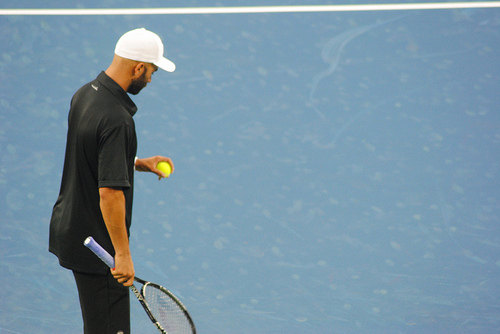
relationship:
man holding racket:
[48, 28, 160, 334] [82, 235, 196, 334]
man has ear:
[48, 28, 160, 334] [134, 62, 145, 77]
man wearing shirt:
[48, 28, 160, 334] [48, 72, 139, 275]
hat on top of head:
[113, 25, 177, 73] [114, 56, 159, 96]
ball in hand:
[156, 163, 171, 178] [134, 156, 175, 183]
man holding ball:
[48, 28, 160, 334] [156, 163, 171, 178]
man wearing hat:
[48, 28, 160, 334] [113, 25, 177, 73]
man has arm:
[48, 28, 160, 334] [95, 186, 135, 286]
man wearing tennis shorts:
[48, 28, 160, 334] [72, 269, 132, 334]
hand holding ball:
[134, 156, 175, 183] [156, 163, 171, 178]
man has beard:
[48, 28, 160, 334] [127, 67, 147, 95]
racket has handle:
[82, 235, 196, 334] [83, 236, 116, 270]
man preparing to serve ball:
[48, 28, 160, 334] [156, 163, 171, 178]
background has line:
[1, 1, 498, 334] [1, 3, 498, 16]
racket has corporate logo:
[82, 235, 196, 334] [157, 295, 185, 330]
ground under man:
[1, 1, 498, 334] [48, 28, 160, 334]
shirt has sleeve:
[48, 72, 139, 275] [99, 130, 132, 188]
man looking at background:
[48, 28, 160, 334] [1, 1, 498, 334]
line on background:
[1, 3, 498, 16] [1, 1, 498, 334]